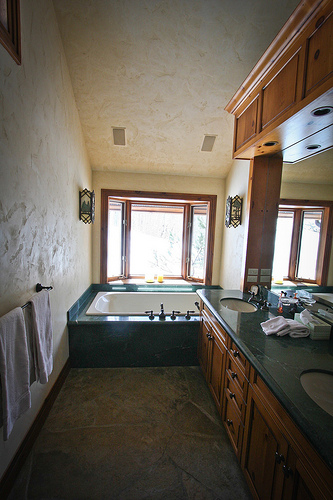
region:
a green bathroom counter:
[193, 279, 331, 402]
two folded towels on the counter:
[260, 314, 307, 336]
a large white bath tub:
[94, 286, 202, 325]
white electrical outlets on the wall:
[246, 261, 260, 286]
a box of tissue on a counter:
[301, 310, 331, 340]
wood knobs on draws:
[216, 350, 241, 440]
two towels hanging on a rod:
[0, 274, 55, 353]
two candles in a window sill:
[136, 272, 169, 284]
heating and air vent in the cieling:
[191, 128, 225, 164]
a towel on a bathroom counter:
[259, 314, 290, 334]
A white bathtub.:
[88, 292, 202, 315]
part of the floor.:
[84, 404, 163, 459]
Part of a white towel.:
[6, 322, 23, 378]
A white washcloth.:
[260, 315, 288, 334]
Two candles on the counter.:
[144, 272, 162, 282]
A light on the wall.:
[76, 186, 94, 225]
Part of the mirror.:
[289, 188, 317, 248]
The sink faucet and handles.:
[246, 291, 271, 311]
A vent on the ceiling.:
[109, 125, 128, 148]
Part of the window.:
[132, 209, 184, 256]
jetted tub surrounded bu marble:
[67, 282, 211, 367]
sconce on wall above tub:
[222, 193, 243, 228]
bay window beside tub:
[98, 188, 215, 286]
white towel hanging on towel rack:
[27, 288, 55, 384]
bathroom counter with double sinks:
[197, 287, 332, 466]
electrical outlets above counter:
[246, 266, 270, 285]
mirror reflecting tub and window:
[270, 123, 328, 293]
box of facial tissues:
[294, 310, 331, 342]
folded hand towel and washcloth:
[260, 315, 309, 340]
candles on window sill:
[144, 268, 165, 283]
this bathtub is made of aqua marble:
[66, 279, 202, 365]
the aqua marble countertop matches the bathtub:
[196, 286, 332, 472]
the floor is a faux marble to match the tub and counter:
[14, 364, 241, 499]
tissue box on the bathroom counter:
[292, 309, 331, 340]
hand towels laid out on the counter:
[257, 313, 309, 339]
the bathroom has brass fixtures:
[142, 300, 196, 319]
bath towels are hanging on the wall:
[2, 283, 54, 440]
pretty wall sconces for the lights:
[223, 193, 243, 229]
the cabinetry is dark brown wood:
[199, 302, 330, 496]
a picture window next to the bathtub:
[101, 189, 218, 287]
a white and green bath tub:
[83, 278, 235, 340]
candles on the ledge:
[136, 264, 169, 284]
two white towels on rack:
[1, 285, 71, 413]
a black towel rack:
[0, 279, 71, 338]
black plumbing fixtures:
[242, 283, 277, 319]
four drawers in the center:
[210, 345, 246, 445]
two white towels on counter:
[259, 307, 315, 369]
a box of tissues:
[284, 305, 323, 340]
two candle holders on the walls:
[71, 173, 258, 230]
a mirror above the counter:
[266, 149, 330, 310]